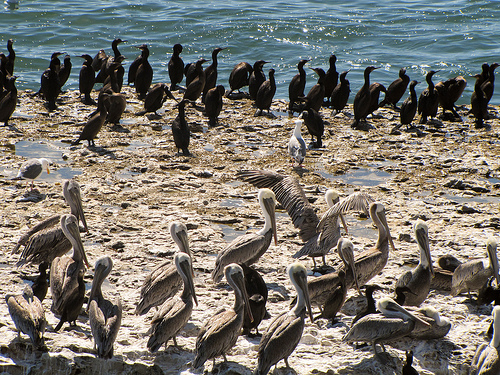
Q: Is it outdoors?
A: Yes, it is outdoors.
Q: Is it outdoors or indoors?
A: It is outdoors.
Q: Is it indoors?
A: No, it is outdoors.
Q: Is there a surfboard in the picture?
A: No, there are no surfboards.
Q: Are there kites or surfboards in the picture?
A: No, there are no surfboards or kites.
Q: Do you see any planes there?
A: No, there are no planes.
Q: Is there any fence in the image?
A: No, there are no fences.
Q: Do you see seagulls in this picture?
A: Yes, there is a seagull.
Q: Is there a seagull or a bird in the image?
A: Yes, there is a seagull.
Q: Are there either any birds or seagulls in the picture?
A: Yes, there is a seagull.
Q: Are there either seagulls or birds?
A: Yes, there is a seagull.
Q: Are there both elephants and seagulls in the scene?
A: No, there is a seagull but no elephants.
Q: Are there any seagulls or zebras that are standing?
A: Yes, the seagull is standing.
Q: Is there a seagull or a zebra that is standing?
A: Yes, the seagull is standing.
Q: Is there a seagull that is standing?
A: Yes, there is a seagull that is standing.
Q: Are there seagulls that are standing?
A: Yes, there is a seagull that is standing.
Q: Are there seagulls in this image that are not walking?
A: Yes, there is a seagull that is standing.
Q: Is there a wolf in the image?
A: No, there are no wolves.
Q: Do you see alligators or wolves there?
A: No, there are no wolves or alligators.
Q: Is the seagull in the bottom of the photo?
A: Yes, the seagull is in the bottom of the image.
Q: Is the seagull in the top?
A: No, the seagull is in the bottom of the image.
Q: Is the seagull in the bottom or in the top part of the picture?
A: The seagull is in the bottom of the image.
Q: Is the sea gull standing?
A: Yes, the sea gull is standing.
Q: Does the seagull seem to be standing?
A: Yes, the seagull is standing.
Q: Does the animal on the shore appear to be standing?
A: Yes, the seagull is standing.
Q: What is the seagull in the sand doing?
A: The seagull is standing.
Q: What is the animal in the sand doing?
A: The seagull is standing.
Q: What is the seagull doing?
A: The seagull is standing.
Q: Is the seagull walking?
A: No, the seagull is standing.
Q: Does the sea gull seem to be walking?
A: No, the sea gull is standing.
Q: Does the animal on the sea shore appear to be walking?
A: No, the sea gull is standing.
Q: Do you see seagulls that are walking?
A: No, there is a seagull but it is standing.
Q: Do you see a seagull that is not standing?
A: No, there is a seagull but it is standing.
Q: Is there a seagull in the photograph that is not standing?
A: No, there is a seagull but it is standing.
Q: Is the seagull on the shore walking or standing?
A: The sea gull is standing.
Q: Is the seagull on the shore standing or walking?
A: The sea gull is standing.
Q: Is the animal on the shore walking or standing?
A: The sea gull is standing.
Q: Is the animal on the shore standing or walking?
A: The sea gull is standing.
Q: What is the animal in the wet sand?
A: The animal is a seagull.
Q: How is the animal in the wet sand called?
A: The animal is a seagull.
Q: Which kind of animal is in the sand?
A: The animal is a seagull.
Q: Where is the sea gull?
A: The sea gull is in the sand.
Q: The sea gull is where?
A: The sea gull is in the sand.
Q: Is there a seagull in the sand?
A: Yes, there is a seagull in the sand.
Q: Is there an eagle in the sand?
A: No, there is a seagull in the sand.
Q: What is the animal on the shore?
A: The animal is a seagull.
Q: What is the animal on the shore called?
A: The animal is a seagull.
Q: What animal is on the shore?
A: The animal is a seagull.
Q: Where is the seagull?
A: The seagull is on the shore.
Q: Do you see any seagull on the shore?
A: Yes, there is a seagull on the shore.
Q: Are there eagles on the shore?
A: No, there is a seagull on the shore.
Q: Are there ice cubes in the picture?
A: No, there are no ice cubes.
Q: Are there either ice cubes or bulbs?
A: No, there are no ice cubes or bulbs.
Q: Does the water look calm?
A: Yes, the water is calm.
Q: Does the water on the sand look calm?
A: Yes, the water is calm.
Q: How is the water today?
A: The water is calm.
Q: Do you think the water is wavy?
A: No, the water is calm.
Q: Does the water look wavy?
A: No, the water is calm.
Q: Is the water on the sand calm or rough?
A: The water is calm.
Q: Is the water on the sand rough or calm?
A: The water is calm.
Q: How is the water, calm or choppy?
A: The water is calm.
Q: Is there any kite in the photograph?
A: No, there are no kites.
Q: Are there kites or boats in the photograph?
A: No, there are no kites or boats.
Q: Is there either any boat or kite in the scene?
A: No, there are no kites or boats.